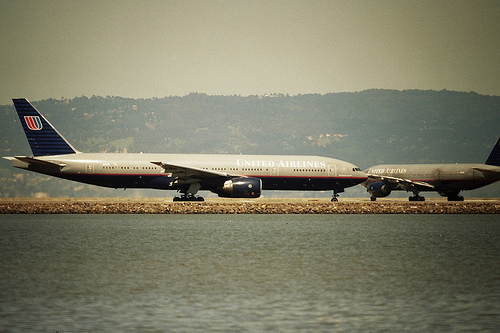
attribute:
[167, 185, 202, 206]
gear — rear landing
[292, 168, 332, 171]
windows — passenger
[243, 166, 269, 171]
windows — passenger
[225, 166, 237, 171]
windows — passenger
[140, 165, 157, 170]
windows — passenger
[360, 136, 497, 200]
airplane — large 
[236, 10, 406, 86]
sky — overcast, dusty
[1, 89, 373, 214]
plane — large 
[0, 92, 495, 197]
trees — in the distance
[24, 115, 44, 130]
logo — red and blue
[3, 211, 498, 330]
water — Blue and calm